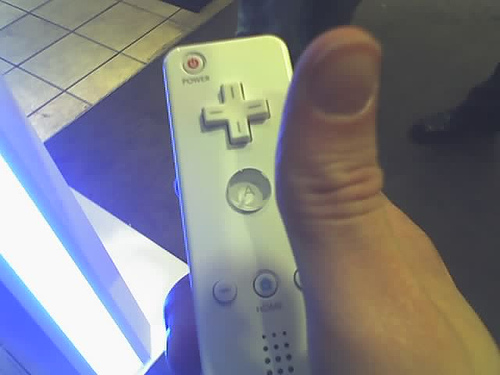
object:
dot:
[261, 335, 267, 340]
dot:
[270, 332, 278, 338]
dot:
[281, 328, 289, 338]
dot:
[262, 344, 269, 350]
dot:
[275, 344, 280, 349]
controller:
[161, 33, 312, 375]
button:
[213, 278, 238, 303]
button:
[254, 272, 278, 297]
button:
[202, 82, 269, 145]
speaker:
[260, 331, 295, 375]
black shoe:
[408, 64, 499, 146]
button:
[213, 269, 302, 304]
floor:
[0, 0, 238, 144]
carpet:
[43, 0, 355, 266]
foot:
[407, 112, 485, 146]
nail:
[306, 46, 379, 116]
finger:
[273, 25, 419, 292]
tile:
[1, 0, 234, 144]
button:
[226, 168, 271, 213]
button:
[181, 52, 207, 74]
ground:
[0, 1, 500, 348]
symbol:
[190, 60, 197, 67]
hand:
[163, 25, 500, 375]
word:
[182, 75, 211, 85]